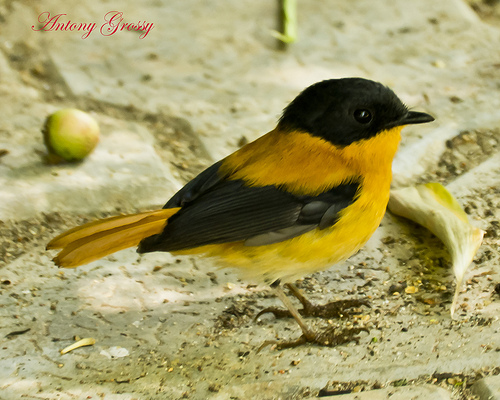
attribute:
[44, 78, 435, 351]
bird — small, yellow, black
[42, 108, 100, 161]
fruit — round, not ripe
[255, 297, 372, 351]
feet — brown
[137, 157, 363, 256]
feathers — black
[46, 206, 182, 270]
feather — yellow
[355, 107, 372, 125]
eye — black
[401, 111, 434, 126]
beak — black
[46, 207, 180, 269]
tail — yellow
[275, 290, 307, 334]
leg — brown